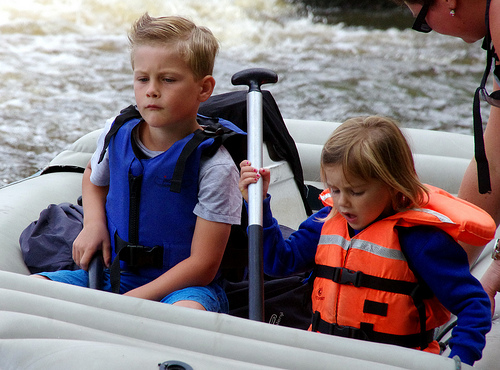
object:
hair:
[126, 12, 218, 78]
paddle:
[230, 65, 277, 324]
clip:
[333, 267, 362, 288]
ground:
[418, 158, 463, 189]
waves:
[290, 24, 474, 117]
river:
[2, 0, 495, 179]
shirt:
[87, 114, 243, 283]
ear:
[442, 1, 460, 16]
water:
[0, 3, 494, 188]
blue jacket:
[103, 117, 249, 292]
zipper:
[127, 163, 142, 245]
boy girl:
[29, 12, 491, 366]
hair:
[312, 115, 430, 226]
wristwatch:
[491, 238, 499, 261]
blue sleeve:
[403, 224, 493, 365]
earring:
[449, 10, 455, 17]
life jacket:
[304, 183, 497, 356]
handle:
[231, 68, 279, 86]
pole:
[245, 90, 265, 322]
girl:
[235, 115, 497, 366]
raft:
[0, 116, 496, 369]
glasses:
[410, 0, 436, 33]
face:
[409, 2, 476, 45]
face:
[491, 238, 500, 258]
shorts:
[36, 269, 230, 313]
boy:
[27, 12, 244, 313]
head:
[128, 10, 219, 128]